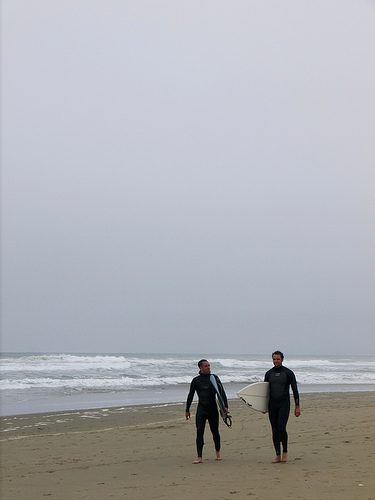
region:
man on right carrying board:
[237, 350, 313, 466]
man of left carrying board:
[183, 356, 237, 464]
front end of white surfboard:
[237, 379, 272, 417]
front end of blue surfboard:
[205, 373, 229, 409]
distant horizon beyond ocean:
[1, 344, 373, 362]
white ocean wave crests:
[1, 352, 373, 395]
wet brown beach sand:
[2, 387, 372, 498]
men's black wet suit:
[257, 365, 304, 456]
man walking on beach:
[181, 355, 235, 463]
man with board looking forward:
[234, 348, 311, 466]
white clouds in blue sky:
[7, 13, 58, 79]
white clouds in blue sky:
[17, 92, 77, 175]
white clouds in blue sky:
[42, 172, 88, 234]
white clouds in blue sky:
[67, 249, 129, 322]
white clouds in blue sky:
[135, 261, 188, 321]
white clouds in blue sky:
[196, 272, 262, 332]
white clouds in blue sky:
[250, 206, 303, 264]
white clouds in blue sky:
[135, 165, 202, 227]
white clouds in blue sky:
[182, 144, 253, 224]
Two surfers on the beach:
[180, 346, 305, 473]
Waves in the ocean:
[1, 351, 373, 393]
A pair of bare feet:
[269, 446, 293, 467]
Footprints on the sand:
[2, 424, 371, 496]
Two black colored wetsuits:
[182, 366, 303, 458]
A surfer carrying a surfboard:
[235, 348, 306, 467]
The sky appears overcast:
[1, 1, 373, 356]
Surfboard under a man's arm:
[205, 365, 237, 432]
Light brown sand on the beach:
[1, 390, 373, 498]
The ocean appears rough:
[1, 349, 373, 415]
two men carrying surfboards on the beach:
[169, 340, 311, 468]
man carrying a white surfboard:
[239, 344, 309, 468]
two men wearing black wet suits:
[170, 339, 305, 459]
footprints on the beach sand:
[294, 417, 357, 468]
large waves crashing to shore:
[15, 344, 125, 405]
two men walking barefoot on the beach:
[174, 438, 306, 481]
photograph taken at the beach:
[17, 202, 369, 480]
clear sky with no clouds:
[66, 217, 317, 306]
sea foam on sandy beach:
[27, 403, 116, 432]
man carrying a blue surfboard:
[181, 348, 235, 466]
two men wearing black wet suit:
[163, 334, 325, 491]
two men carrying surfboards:
[152, 340, 313, 488]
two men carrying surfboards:
[171, 331, 296, 479]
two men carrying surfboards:
[158, 305, 319, 498]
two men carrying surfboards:
[147, 327, 318, 487]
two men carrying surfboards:
[170, 341, 300, 468]